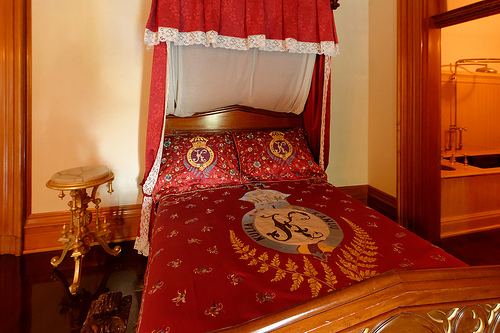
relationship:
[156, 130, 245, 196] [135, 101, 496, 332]
pillow on a bed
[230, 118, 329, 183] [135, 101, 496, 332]
pillow on a bed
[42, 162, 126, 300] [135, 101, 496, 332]
table near a bed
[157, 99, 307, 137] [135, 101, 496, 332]
headboard of a bed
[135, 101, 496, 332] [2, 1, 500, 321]
bed in a bedroom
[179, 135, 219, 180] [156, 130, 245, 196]
design on a pillow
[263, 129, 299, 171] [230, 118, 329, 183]
design on a pillow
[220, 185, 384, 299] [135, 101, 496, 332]
design on a bed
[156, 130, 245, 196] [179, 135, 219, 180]
pillow has design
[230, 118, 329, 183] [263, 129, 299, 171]
pillow has design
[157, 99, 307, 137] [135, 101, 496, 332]
headboard on bed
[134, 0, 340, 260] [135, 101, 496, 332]
curtain hanging above bed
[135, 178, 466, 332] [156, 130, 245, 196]
blanket matches pillow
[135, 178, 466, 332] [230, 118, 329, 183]
blanket matches pillow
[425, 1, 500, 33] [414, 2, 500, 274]
beam in doorway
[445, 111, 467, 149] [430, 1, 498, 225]
fixture in bathroom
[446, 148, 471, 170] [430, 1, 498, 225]
fixture in bathroom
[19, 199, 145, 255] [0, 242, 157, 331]
baseboard runs along floor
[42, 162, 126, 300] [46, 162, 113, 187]
table has top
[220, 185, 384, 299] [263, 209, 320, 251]
logo has a k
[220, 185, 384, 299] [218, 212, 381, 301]
logo has a wreath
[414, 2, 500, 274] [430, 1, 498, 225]
doorway to bathroom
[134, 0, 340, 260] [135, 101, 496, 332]
curtain on top of bed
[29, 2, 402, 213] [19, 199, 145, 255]
wall has baseboard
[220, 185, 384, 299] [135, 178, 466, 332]
design on blanket